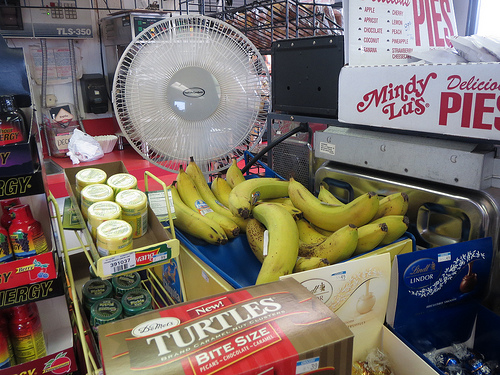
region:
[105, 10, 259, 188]
a white fan blowing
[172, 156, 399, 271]
13 ripe bananas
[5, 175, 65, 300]
a small energy drink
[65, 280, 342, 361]
box of bite size candy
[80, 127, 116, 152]
white coffee filters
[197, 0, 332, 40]
a metal tray of bread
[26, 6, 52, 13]
a green light on a machine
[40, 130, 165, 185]
red table behind under the fan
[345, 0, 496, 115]
red and white box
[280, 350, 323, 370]
the price is 33 cents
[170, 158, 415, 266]
green and yellow bananas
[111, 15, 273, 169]
white fan blowing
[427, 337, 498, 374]
chocolate in blue wrappers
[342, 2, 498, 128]
pies in white box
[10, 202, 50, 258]
energy drink in red and yellow bottle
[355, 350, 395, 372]
chocolate in white and gold wrapper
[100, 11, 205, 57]
coffee machines behind fan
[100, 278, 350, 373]
brown and red turtle box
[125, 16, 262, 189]
white fan behind bananas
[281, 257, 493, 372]
blue and white chocolate boxes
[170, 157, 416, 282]
The bananas are yellow.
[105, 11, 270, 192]
The fan is white.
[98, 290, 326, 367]
The box says turtles on it.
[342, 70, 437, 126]
The text says Mindy Lu's.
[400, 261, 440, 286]
The text says Lindor.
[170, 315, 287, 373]
The text says bite size.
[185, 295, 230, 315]
The word new is on the box.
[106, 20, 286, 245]
A fan next to bananas.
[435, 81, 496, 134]
The word pies is on the box.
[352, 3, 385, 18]
The red text says the word apple.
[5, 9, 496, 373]
items at a convenience store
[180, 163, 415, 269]
yellow bananas in crate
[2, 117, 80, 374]
five hour energy shots in case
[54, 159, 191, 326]
gum in boxes for sale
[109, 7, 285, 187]
white fan on counter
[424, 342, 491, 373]
wrapped chocolates in box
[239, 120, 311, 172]
black wire behind microwave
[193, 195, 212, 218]
sticker on a banana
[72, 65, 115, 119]
soap dispenser on a wall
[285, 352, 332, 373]
price sticker on Turtle's box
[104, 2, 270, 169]
The fan is on.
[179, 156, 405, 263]
A bunch of bannanas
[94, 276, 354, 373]
Turtle bite size chocolate pecans.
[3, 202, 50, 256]
A five hour energy.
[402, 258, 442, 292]
Lindor truffle logo on box.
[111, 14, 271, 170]
The fan is white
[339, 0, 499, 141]
A box of mindy lu's pies.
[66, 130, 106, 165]
A bag of trash.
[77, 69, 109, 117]
A black wall mounted object.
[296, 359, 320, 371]
The turtles are priced thirty nine cents.